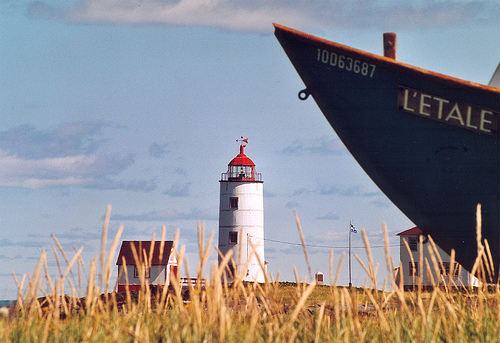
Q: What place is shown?
A: It is a field.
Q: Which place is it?
A: It is a field.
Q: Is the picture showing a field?
A: Yes, it is showing a field.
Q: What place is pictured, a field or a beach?
A: It is a field.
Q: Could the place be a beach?
A: No, it is a field.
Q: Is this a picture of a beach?
A: No, the picture is showing a field.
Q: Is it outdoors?
A: Yes, it is outdoors.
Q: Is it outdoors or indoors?
A: It is outdoors.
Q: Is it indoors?
A: No, it is outdoors.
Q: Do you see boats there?
A: Yes, there is a boat.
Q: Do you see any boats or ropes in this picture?
A: Yes, there is a boat.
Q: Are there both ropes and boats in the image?
A: No, there is a boat but no ropes.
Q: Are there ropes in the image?
A: No, there are no ropes.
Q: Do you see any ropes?
A: No, there are no ropes.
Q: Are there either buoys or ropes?
A: No, there are no ropes or buoys.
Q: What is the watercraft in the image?
A: The watercraft is a boat.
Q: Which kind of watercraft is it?
A: The watercraft is a boat.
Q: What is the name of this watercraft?
A: This is a boat.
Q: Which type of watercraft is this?
A: This is a boat.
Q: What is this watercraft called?
A: This is a boat.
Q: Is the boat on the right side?
A: Yes, the boat is on the right of the image.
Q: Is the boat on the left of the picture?
A: No, the boat is on the right of the image.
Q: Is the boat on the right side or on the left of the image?
A: The boat is on the right of the image.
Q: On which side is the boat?
A: The boat is on the right of the image.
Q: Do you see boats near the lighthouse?
A: Yes, there is a boat near the lighthouse.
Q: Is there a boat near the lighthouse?
A: Yes, there is a boat near the lighthouse.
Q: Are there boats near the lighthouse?
A: Yes, there is a boat near the lighthouse.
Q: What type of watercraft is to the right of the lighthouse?
A: The watercraft is a boat.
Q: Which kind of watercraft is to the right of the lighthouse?
A: The watercraft is a boat.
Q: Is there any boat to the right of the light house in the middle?
A: Yes, there is a boat to the right of the light house.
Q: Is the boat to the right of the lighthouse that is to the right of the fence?
A: Yes, the boat is to the right of the lighthouse.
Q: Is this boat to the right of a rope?
A: No, the boat is to the right of the lighthouse.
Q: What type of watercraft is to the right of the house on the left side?
A: The watercraft is a boat.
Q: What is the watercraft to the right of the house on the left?
A: The watercraft is a boat.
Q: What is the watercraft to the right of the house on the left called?
A: The watercraft is a boat.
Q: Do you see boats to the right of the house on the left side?
A: Yes, there is a boat to the right of the house.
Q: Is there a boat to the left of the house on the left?
A: No, the boat is to the right of the house.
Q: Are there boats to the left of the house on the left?
A: No, the boat is to the right of the house.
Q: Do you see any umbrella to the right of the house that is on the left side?
A: No, there is a boat to the right of the house.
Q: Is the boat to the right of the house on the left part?
A: Yes, the boat is to the right of the house.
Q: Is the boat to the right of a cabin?
A: No, the boat is to the right of the house.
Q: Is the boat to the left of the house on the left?
A: No, the boat is to the right of the house.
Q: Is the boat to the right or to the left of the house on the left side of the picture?
A: The boat is to the right of the house.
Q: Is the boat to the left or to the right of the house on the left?
A: The boat is to the right of the house.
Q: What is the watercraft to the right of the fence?
A: The watercraft is a boat.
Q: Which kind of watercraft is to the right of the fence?
A: The watercraft is a boat.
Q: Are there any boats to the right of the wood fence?
A: Yes, there is a boat to the right of the fence.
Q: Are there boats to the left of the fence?
A: No, the boat is to the right of the fence.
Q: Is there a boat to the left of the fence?
A: No, the boat is to the right of the fence.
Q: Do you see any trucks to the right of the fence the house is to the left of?
A: No, there is a boat to the right of the fence.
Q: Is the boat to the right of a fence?
A: Yes, the boat is to the right of a fence.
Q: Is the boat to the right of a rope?
A: No, the boat is to the right of a fence.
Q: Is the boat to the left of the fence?
A: No, the boat is to the right of the fence.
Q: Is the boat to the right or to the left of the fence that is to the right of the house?
A: The boat is to the right of the fence.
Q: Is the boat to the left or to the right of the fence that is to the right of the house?
A: The boat is to the right of the fence.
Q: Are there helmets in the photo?
A: No, there are no helmets.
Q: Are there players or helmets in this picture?
A: No, there are no helmets or players.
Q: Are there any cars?
A: No, there are no cars.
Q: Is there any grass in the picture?
A: Yes, there is grass.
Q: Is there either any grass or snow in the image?
A: Yes, there is grass.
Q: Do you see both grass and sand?
A: No, there is grass but no sand.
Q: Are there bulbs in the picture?
A: No, there are no bulbs.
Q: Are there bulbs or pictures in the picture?
A: No, there are no bulbs or pictures.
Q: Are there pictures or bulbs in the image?
A: No, there are no bulbs or pictures.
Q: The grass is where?
A: The grass is on the field.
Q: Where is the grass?
A: The grass is on the field.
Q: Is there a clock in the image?
A: No, there are no clocks.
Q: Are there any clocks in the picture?
A: No, there are no clocks.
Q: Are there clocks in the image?
A: No, there are no clocks.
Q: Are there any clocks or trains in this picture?
A: No, there are no clocks or trains.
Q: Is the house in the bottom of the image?
A: Yes, the house is in the bottom of the image.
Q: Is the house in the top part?
A: No, the house is in the bottom of the image.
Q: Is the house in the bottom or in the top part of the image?
A: The house is in the bottom of the image.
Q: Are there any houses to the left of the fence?
A: Yes, there is a house to the left of the fence.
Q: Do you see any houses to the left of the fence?
A: Yes, there is a house to the left of the fence.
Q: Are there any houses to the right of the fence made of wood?
A: No, the house is to the left of the fence.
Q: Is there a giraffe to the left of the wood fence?
A: No, there is a house to the left of the fence.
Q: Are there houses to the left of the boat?
A: Yes, there is a house to the left of the boat.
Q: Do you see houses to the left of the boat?
A: Yes, there is a house to the left of the boat.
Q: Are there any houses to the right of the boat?
A: No, the house is to the left of the boat.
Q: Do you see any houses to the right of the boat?
A: No, the house is to the left of the boat.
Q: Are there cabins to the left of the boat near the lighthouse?
A: No, there is a house to the left of the boat.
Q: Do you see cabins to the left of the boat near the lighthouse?
A: No, there is a house to the left of the boat.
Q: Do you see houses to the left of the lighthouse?
A: Yes, there is a house to the left of the lighthouse.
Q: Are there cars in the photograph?
A: No, there are no cars.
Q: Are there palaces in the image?
A: No, there are no palaces.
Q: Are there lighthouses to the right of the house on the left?
A: Yes, there is a lighthouse to the right of the house.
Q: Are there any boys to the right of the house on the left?
A: No, there is a lighthouse to the right of the house.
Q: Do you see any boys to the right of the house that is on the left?
A: No, there is a lighthouse to the right of the house.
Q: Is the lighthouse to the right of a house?
A: Yes, the lighthouse is to the right of a house.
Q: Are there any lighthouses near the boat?
A: Yes, there is a lighthouse near the boat.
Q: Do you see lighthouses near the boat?
A: Yes, there is a lighthouse near the boat.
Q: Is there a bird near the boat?
A: No, there is a lighthouse near the boat.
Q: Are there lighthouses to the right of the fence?
A: Yes, there is a lighthouse to the right of the fence.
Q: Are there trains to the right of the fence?
A: No, there is a lighthouse to the right of the fence.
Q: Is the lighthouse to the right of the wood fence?
A: Yes, the lighthouse is to the right of the fence.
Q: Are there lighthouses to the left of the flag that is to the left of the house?
A: Yes, there is a lighthouse to the left of the flag.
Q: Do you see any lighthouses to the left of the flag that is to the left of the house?
A: Yes, there is a lighthouse to the left of the flag.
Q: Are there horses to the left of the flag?
A: No, there is a lighthouse to the left of the flag.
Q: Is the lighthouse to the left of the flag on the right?
A: Yes, the lighthouse is to the left of the flag.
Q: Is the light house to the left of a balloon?
A: No, the light house is to the left of the flag.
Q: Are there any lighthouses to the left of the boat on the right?
A: Yes, there is a lighthouse to the left of the boat.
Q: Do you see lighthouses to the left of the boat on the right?
A: Yes, there is a lighthouse to the left of the boat.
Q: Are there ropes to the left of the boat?
A: No, there is a lighthouse to the left of the boat.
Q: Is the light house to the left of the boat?
A: Yes, the light house is to the left of the boat.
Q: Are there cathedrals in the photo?
A: No, there are no cathedrals.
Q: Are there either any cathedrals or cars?
A: No, there are no cathedrals or cars.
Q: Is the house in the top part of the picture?
A: No, the house is in the bottom of the image.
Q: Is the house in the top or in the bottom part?
A: The house is in the bottom of the image.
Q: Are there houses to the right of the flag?
A: Yes, there is a house to the right of the flag.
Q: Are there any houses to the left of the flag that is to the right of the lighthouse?
A: No, the house is to the right of the flag.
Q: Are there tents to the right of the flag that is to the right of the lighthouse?
A: No, there is a house to the right of the flag.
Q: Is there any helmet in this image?
A: No, there are no helmets.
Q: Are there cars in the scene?
A: No, there are no cars.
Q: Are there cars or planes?
A: No, there are no cars or planes.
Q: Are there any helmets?
A: No, there are no helmets.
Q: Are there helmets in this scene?
A: No, there are no helmets.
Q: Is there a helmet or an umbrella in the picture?
A: No, there are no helmets or umbrellas.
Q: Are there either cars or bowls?
A: No, there are no cars or bowls.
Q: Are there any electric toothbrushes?
A: No, there are no electric toothbrushes.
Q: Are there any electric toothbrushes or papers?
A: No, there are no electric toothbrushes or papers.